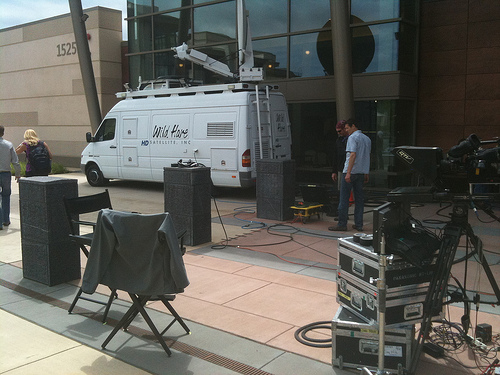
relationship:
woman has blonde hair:
[7, 125, 53, 175] [19, 125, 47, 144]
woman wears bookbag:
[7, 125, 53, 175] [21, 143, 52, 178]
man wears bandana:
[328, 116, 345, 229] [334, 117, 347, 132]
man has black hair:
[341, 118, 372, 237] [344, 116, 359, 133]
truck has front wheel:
[80, 73, 304, 190] [80, 162, 109, 189]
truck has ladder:
[80, 73, 304, 190] [246, 76, 277, 159]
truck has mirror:
[80, 73, 304, 190] [84, 130, 98, 144]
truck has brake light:
[80, 73, 304, 190] [240, 145, 252, 171]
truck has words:
[80, 73, 304, 190] [141, 122, 194, 148]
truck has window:
[80, 73, 304, 190] [84, 117, 117, 150]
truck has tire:
[80, 73, 304, 190] [80, 162, 109, 189]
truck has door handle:
[80, 73, 304, 190] [106, 142, 121, 155]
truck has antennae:
[80, 73, 304, 190] [168, 1, 263, 86]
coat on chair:
[76, 192, 188, 319] [89, 204, 197, 366]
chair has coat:
[89, 204, 197, 366] [76, 192, 188, 319]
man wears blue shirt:
[341, 118, 372, 237] [339, 131, 375, 178]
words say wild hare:
[141, 122, 194, 148] [152, 122, 190, 141]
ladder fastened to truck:
[246, 76, 277, 159] [80, 73, 304, 190]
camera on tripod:
[383, 129, 495, 214] [408, 194, 498, 370]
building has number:
[1, 9, 147, 185] [50, 38, 81, 60]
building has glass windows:
[112, 0, 498, 197] [134, 0, 400, 84]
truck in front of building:
[80, 73, 304, 190] [112, 0, 498, 197]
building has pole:
[112, 0, 498, 197] [59, 0, 97, 137]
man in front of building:
[328, 116, 345, 229] [112, 0, 498, 197]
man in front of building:
[341, 118, 372, 237] [112, 0, 498, 197]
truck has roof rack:
[80, 73, 304, 190] [112, 74, 276, 100]